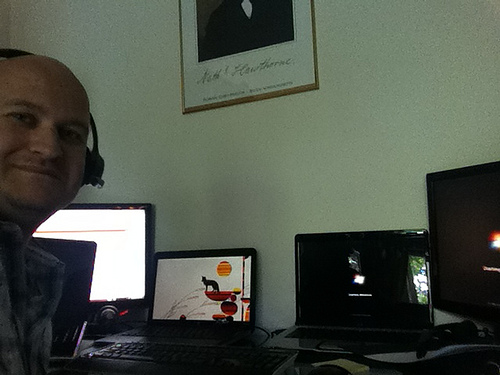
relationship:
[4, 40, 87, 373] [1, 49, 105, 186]
man wearing headphones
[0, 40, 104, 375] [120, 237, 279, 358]
man in front of computer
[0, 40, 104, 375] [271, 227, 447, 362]
man in front of computer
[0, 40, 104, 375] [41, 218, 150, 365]
man in front of computer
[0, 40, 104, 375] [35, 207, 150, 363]
man in front of computer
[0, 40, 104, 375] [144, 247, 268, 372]
man in front of computer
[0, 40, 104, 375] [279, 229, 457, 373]
man in front of computer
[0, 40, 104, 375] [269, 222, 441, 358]
man in front of computer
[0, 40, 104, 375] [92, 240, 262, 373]
man in front of computer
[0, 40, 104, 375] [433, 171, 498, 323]
man in front of computer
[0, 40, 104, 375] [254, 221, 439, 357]
man in front of computer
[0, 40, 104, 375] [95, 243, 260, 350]
man in front of computer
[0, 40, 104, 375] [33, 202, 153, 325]
man in front of computer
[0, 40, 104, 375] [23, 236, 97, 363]
man in front of computer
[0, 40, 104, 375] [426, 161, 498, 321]
man in front of computer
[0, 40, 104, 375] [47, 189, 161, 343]
man in front of computer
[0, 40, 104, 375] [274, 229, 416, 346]
man in front of computer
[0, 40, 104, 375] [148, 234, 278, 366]
man in front of computer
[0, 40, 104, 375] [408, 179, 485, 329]
man in front of computer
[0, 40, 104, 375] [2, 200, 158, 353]
man in front of computer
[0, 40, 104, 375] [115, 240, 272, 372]
man in front of computer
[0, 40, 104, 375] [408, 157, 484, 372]
man in front of computer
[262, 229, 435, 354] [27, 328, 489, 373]
computer on a desk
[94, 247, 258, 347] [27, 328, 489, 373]
computer on a desk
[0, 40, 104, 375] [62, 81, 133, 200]
man wearing headphones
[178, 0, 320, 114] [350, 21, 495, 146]
photo on a wall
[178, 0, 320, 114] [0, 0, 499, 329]
photo on wall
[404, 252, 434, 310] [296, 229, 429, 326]
reflection in screen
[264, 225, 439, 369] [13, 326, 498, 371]
computer on a desk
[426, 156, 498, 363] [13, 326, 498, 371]
computer on a desk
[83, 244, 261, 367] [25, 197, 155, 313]
computer on a computer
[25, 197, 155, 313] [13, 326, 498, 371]
computer on a desk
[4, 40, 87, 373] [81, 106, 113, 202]
man with headphones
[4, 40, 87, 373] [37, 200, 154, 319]
man in front of computer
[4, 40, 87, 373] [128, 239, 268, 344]
man in front of computer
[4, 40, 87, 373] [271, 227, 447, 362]
man in front of computer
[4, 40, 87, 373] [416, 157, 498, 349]
man in front of computer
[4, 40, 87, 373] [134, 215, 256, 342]
man in front of computer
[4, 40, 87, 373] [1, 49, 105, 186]
man with headphones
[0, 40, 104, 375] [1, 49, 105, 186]
man with headphones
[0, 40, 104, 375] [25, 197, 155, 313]
man in front of computer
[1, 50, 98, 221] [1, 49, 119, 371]
head of a man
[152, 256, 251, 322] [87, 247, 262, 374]
computer screen of a laptop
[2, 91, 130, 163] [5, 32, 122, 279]
eyes of a man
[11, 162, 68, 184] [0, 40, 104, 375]
mouth of a man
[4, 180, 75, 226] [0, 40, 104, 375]
chin of a man